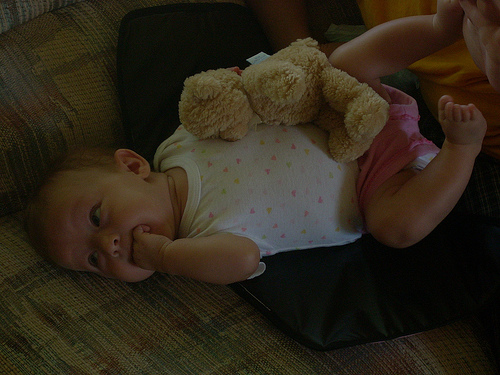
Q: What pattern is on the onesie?
A: Hearts.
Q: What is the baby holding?
A: A teddy bear.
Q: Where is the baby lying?
A: On the sofa.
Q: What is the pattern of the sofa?
A: Plaid.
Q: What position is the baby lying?
A: On her back.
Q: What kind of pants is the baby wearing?
A: Pink shorts.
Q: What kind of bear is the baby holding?
A: A stuffed bear.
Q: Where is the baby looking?
A: To the left.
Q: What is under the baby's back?
A: A pillow.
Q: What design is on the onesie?
A: Hearts.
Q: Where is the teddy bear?
A: Stomach.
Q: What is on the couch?
A: Baby.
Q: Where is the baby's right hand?
A: Mouth.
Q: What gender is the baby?
A: Girl.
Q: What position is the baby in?
A: Lying.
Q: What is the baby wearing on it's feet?
A: Nothing.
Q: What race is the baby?
A: Caucasian.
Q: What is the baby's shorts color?
A: Pink.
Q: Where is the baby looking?
A: To the left.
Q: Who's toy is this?
A: The baby.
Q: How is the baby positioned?
A: Her back.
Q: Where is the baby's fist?
A: In her mouth.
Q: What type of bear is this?
A: Small and stuffed.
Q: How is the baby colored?
A: Light brown.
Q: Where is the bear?
A: Baby's arm.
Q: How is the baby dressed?
A: White shirt.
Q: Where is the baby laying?
A: Changing pad.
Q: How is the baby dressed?
A: Pink shorts.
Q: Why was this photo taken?
A: To show off the baby.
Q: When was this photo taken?
A: While the baby was awake.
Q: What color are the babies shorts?
A: Pink.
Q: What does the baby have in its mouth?
A: Its hand.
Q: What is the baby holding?
A: A teddy bear.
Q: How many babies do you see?
A: One.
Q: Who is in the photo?
A: A baby girl.